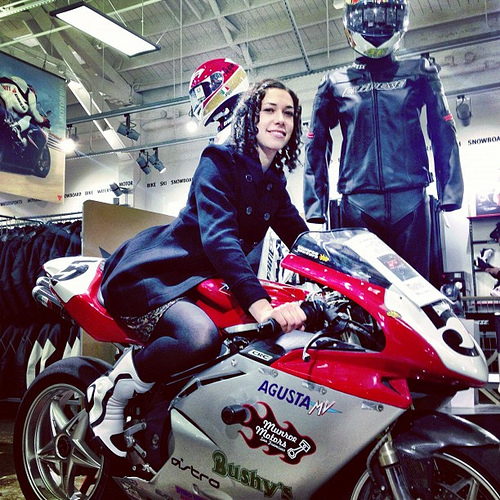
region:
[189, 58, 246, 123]
Red shiny helmet reflecting light.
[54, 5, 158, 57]
Light fixture hanging from ceiling.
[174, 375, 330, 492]
Various name brands on motorcycle.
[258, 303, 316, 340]
Hand on handle bar.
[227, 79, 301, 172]
Girl with curly hair.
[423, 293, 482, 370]
The number 5 on bike.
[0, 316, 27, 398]
Black jackets for sale.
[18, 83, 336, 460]
Girl on motor bike.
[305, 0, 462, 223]
Motorcycle gear on display.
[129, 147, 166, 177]
Light fixture pointed towards wall.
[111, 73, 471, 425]
a woman on a bike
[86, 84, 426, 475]
a woman on a motorcycle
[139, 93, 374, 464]
a woman in a store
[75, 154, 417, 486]
a motorcycle in a store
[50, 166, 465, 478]
a motorcycle that is on display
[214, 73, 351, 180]
a woman with curly hair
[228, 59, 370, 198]
a woma with black curly hair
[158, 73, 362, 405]
a woman wearing a jacket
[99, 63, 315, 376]
a woman wearing a long jacket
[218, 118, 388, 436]
a woman wearing boots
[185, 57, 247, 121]
a red and brown bike helmet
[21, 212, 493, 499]
a red and white motorcycle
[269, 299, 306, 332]
the hand of a man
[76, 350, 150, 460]
a woman's black and white boot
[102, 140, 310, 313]
a woman's black coat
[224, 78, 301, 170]
a woman's curly black hair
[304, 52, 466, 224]
a black motorcycle jacket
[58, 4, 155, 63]
a long light fixture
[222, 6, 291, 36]
part of a ceiling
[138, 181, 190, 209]
part of a white wall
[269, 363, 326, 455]
This sign on this motorcycle says Agusta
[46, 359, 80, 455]
There is a large, black tire here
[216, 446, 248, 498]
This says "Bushy's" on the side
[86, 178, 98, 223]
There is a white wall here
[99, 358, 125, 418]
There is a white boot pictured here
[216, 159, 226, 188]
This woman is wearing a coat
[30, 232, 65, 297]
There are coats pictured in the background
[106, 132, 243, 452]
This photo has a great deal of detail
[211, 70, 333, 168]
head of the lady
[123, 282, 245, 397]
leg of the lady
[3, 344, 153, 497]
back tire of the bike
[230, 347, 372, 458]
red and white bike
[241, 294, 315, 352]
hand of the lady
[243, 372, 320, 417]
word on the bike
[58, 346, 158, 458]
white boot on foot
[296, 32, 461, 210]
outfit next to lady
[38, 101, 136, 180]
light in the photo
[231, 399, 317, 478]
sticker on the bike